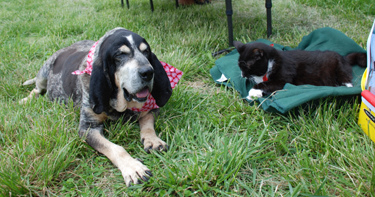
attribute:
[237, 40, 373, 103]
cat — black, white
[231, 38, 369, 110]
cat — black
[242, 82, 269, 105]
paws — white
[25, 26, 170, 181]
dog — laying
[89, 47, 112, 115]
ear — long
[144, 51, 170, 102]
ear — long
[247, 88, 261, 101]
paws — white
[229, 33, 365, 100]
cat — black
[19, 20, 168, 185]
dog — black, white, brown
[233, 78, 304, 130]
paw — furry, white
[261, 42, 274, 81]
collar — red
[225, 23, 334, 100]
cat — black, white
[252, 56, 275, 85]
ribbon — thin, red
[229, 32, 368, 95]
cat — black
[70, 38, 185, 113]
scarf — pink, polka dotted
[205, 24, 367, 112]
blanket — green